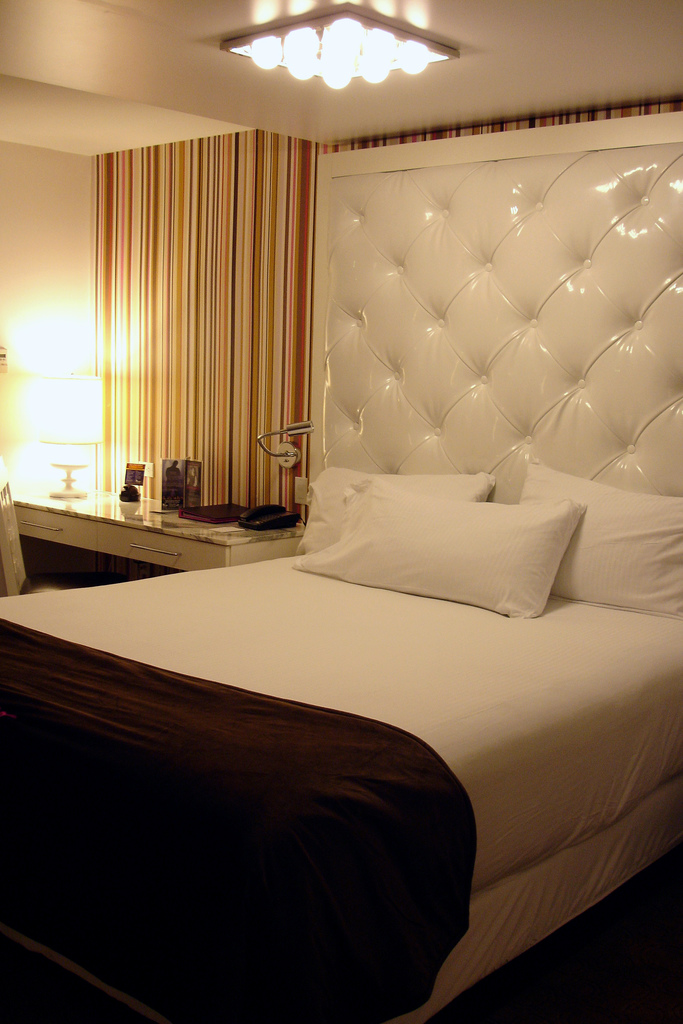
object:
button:
[475, 370, 492, 388]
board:
[313, 116, 676, 484]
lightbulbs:
[247, 33, 286, 74]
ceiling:
[4, 6, 681, 155]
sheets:
[1, 523, 659, 890]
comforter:
[0, 614, 490, 995]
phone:
[238, 504, 301, 531]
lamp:
[32, 370, 104, 503]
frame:
[119, 461, 147, 503]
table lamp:
[34, 370, 105, 504]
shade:
[0, 367, 42, 458]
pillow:
[516, 458, 683, 629]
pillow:
[299, 459, 497, 566]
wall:
[0, 154, 101, 508]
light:
[211, 3, 463, 100]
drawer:
[97, 517, 230, 582]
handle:
[126, 537, 184, 563]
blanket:
[0, 618, 482, 1021]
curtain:
[89, 128, 319, 527]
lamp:
[253, 417, 317, 466]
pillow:
[296, 479, 588, 621]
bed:
[1, 465, 683, 1021]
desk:
[17, 477, 301, 601]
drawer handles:
[15, 514, 64, 537]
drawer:
[9, 500, 98, 551]